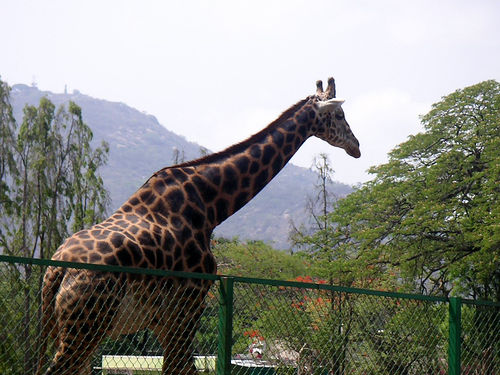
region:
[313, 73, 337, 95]
Two horns on top of giraffe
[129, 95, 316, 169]
Hair on giraffe's neck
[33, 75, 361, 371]
Giraffe is black and brown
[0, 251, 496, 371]
Fence is green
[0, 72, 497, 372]
Giraffe near green fence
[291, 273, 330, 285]
Red flowers on tree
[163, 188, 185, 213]
Black spot on giraffe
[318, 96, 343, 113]
Ear on giraffe's head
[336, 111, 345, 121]
Round eye on giraffe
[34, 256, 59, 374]
Tail on giraffe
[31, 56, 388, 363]
an adult giraffe walking to the right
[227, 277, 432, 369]
a green chain link fence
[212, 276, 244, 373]
a green metal fence post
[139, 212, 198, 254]
unusually dark brown spots on a giraffe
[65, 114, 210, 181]
a large mountain range behind the giraffe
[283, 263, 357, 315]
red autumn leaves on a tree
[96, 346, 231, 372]
a short white building in the background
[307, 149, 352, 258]
a thin tree with no leaves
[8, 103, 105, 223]
a tall willow tree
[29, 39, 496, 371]
a giraffe living in an enclosure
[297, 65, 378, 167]
a giraffes head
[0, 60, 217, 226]
hillside covered in trees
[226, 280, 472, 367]
a green fence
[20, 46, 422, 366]
a brown and yellow zebra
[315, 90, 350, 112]
a brown zebra ear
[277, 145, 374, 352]
a thin dying tree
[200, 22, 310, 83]
bright white sky above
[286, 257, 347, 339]
orange leaves on the trees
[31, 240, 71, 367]
the tail of the zebra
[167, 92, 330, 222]
a long giraffes neck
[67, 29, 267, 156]
the sky is clear and blue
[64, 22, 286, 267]
the sky is clear and blue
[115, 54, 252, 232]
the sky is clear and blue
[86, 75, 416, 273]
Black, yellow, and white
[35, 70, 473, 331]
This is an animal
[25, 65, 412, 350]
The animal is not facing the camera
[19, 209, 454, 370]
Gate is green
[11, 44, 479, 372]
Mountains in the background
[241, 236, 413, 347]
Orange leaves on the tree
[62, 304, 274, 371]
White building in the back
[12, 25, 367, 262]
The hills are high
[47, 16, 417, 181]
Blue is the color of the sky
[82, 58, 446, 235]
It is sunny outside